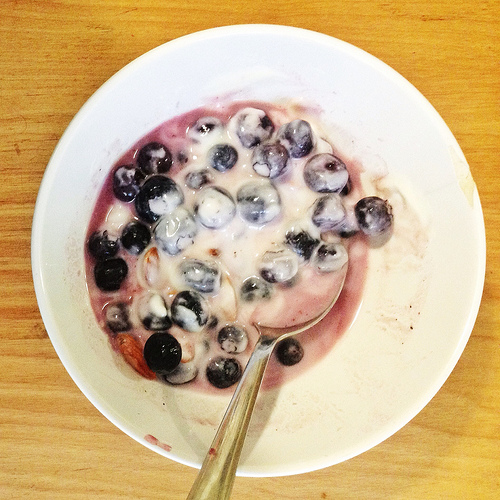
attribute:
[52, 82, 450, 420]
bowl — blueberries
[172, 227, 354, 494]
spoon — silver, metal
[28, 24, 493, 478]
bowl — dessert, serving, small, white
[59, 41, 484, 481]
bowl — white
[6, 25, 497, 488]
food — full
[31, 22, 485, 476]
dish — white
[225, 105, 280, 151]
berry — delicious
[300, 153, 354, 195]
blueberry — six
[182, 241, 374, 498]
spoon — serving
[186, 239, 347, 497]
spoon — silver, color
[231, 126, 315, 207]
blueberry — one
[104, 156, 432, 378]
blueberries — four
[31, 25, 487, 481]
plate — half full, white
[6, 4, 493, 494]
table — brown, light, maple, wooden, serving, wood, colored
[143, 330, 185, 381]
berry — black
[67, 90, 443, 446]
dessert — berry, delicious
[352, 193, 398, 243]
berry — delicious